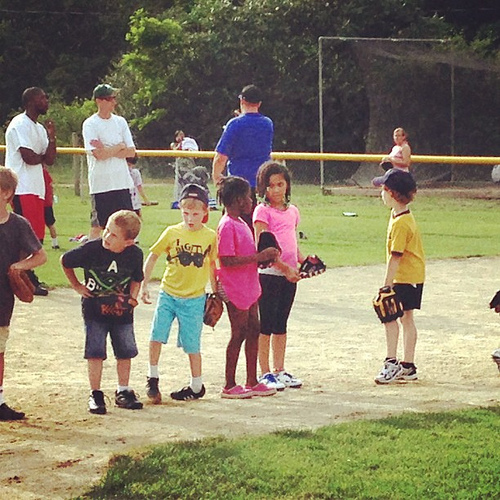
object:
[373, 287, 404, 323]
baseball glove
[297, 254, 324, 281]
baseball glove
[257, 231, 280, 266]
baseball glove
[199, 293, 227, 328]
baseball glove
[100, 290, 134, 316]
baseball glove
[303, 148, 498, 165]
pole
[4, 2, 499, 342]
park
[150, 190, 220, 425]
boy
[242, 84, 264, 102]
cap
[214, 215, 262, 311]
shirt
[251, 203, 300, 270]
shirt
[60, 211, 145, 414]
boy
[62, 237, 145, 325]
t-shirt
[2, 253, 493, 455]
ground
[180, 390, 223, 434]
dirt path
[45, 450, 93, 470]
dirt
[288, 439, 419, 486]
grass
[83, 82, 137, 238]
adult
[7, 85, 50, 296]
adult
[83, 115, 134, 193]
shirt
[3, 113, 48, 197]
shirt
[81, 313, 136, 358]
jean shorts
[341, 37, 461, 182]
tree trunk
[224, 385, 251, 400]
pink shoes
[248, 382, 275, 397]
pink shoes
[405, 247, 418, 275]
yellow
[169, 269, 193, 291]
yellow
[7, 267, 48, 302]
gloves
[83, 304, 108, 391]
leg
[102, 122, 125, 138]
white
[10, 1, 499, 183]
trees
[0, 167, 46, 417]
children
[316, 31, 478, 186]
metal frame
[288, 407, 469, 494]
grass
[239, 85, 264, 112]
head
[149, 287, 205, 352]
shorts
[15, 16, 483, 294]
background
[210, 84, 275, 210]
adult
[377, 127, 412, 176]
adult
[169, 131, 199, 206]
adult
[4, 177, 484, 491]
playing field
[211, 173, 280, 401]
child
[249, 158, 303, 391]
child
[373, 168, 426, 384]
child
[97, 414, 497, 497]
area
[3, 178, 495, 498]
park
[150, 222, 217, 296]
jersey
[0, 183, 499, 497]
field